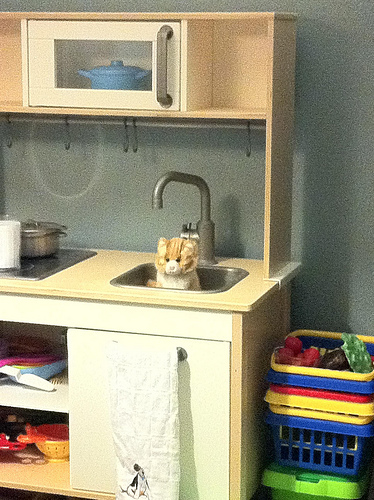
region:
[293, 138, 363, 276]
the wall is grey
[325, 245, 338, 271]
the wall is grey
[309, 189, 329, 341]
the wall is grey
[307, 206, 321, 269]
the wall is grey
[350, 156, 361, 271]
the wall is grey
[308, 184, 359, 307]
the wall is grey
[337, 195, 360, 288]
the wall is grey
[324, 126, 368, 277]
the wall is grey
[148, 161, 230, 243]
the facet is grey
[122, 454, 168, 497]
the dog is white and black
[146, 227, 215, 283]
the stuffed animal is orange and white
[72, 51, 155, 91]
the bowl and lid is blue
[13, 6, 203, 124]
the microwave is white and grey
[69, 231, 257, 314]
the counter is a creamy tan color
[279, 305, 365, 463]
the six baskets are different colors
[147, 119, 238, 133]
the pole is grey in color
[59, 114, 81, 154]
the hook is black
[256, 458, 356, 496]
the plastic tote is neon green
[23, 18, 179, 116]
white microwave with silver handle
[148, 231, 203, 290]
ceramic cat in sink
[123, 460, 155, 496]
black and white dog on white towel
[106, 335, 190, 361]
white towel on silver rack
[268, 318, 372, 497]
multi-colored bins next to sink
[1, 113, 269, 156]
silver hangers on silver rack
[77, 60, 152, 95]
blue teapot in microwave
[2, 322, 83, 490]
left cabinet door open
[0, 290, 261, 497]
wooden counter with white cabinet doors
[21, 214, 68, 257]
silver pot on stove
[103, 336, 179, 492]
the cloth is white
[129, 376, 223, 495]
the cloth is white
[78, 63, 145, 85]
blue teapot in microwave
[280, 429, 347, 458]
Blue bin in stack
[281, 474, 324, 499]
Green bin on bottom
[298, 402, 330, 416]
Yellow bins in stack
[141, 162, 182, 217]
silver faucet on sink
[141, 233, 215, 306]
stuffed animal in sink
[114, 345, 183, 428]
white towel on rack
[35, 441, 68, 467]
yellow strainer in cabinet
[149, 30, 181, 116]
silver handle on microwave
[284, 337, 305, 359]
plastic tomatoes in bin